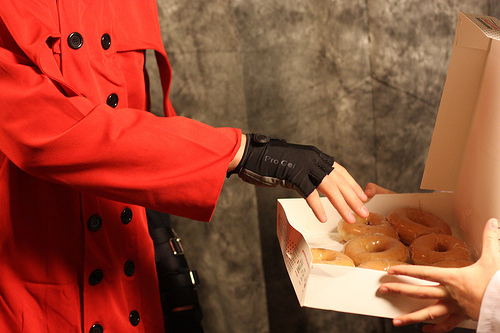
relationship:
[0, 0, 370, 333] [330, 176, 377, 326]
person grabbing donut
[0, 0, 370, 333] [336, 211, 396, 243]
person grabbing donuts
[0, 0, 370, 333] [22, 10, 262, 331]
person has on coat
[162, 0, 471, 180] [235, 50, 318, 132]
wall in background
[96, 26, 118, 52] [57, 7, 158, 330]
button on box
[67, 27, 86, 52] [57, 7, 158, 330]
button on box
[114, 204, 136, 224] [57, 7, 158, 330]
button on box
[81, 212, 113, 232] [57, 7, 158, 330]
button on box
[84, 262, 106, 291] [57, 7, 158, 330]
button on box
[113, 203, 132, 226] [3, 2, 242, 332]
button on a coat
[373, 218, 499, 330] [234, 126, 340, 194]
hand covered with glove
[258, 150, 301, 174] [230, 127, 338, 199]
text on a glove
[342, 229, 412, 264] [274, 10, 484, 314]
donut in a box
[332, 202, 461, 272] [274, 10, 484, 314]
donuts in a box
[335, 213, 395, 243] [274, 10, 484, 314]
donut in a box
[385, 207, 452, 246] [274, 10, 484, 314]
donut in a box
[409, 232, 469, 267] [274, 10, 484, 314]
donut in a box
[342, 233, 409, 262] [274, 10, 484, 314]
dounut in a box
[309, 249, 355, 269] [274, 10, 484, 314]
donut in a box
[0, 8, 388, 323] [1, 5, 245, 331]
person in a jacket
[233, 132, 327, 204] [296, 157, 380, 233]
glove on a person's hand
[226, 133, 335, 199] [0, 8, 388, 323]
glove worn by a person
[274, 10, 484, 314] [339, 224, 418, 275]
box with doughnuts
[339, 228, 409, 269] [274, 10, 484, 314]
dounut in a box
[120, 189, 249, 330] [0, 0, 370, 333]
purse on a person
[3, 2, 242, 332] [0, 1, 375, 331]
coat on a woman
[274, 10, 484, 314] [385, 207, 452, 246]
box of donut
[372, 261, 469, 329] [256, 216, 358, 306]
fingers are holding a box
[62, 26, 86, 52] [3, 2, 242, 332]
button on a coat